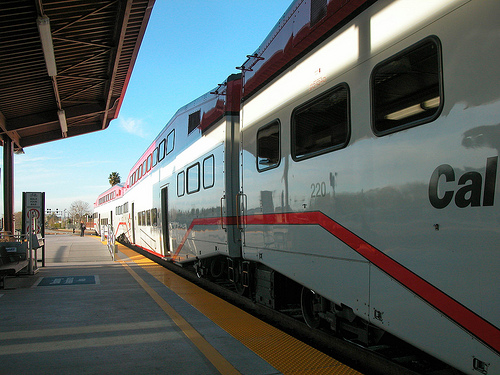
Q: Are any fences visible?
A: No, there are no fences.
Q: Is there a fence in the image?
A: No, there are no fences.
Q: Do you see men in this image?
A: No, there are no men.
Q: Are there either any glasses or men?
A: No, there are no men or glasses.